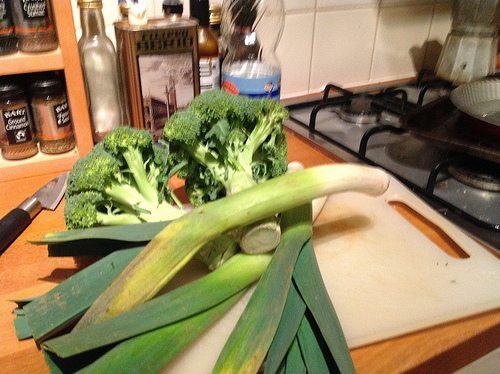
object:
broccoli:
[157, 88, 290, 257]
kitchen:
[2, 2, 496, 372]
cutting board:
[62, 161, 495, 373]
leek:
[16, 164, 397, 373]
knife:
[2, 167, 72, 263]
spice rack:
[1, 1, 95, 185]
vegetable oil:
[213, 2, 292, 115]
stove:
[280, 68, 499, 225]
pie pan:
[447, 73, 499, 132]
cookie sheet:
[399, 103, 497, 159]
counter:
[6, 163, 393, 374]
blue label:
[220, 70, 282, 103]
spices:
[30, 80, 75, 155]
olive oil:
[108, 12, 203, 127]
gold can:
[121, 31, 193, 118]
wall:
[284, 1, 427, 80]